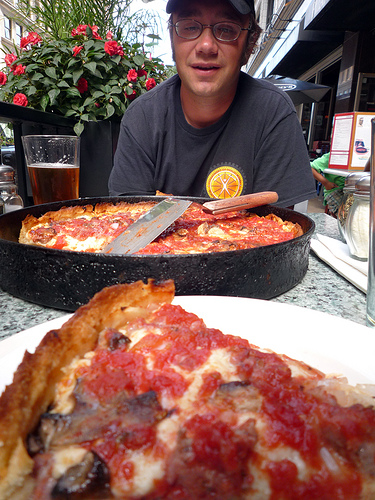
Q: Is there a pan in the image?
A: Yes, there is a pan.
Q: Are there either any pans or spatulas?
A: Yes, there is a pan.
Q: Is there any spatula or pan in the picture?
A: Yes, there is a pan.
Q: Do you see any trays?
A: No, there are no trays.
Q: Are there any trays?
A: No, there are no trays.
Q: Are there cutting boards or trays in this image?
A: No, there are no trays or cutting boards.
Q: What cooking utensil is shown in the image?
A: The cooking utensil is a pan.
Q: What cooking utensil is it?
A: The cooking utensil is a pan.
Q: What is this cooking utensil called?
A: That is a pan.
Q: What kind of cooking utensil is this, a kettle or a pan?
A: That is a pan.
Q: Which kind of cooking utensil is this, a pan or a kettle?
A: That is a pan.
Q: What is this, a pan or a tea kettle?
A: This is a pan.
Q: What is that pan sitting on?
A: The pan is sitting on the pizza.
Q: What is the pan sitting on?
A: The pan is sitting on the pizza.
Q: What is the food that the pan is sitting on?
A: The food is a pizza.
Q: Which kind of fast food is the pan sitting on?
A: The pan is sitting on the pizza.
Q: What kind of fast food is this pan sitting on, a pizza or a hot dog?
A: The pan is sitting on a pizza.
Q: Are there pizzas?
A: Yes, there is a pizza.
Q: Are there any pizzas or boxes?
A: Yes, there is a pizza.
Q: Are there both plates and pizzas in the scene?
A: Yes, there are both a pizza and a plate.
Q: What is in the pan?
A: The pizza is in the pan.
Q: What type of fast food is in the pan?
A: The food is a pizza.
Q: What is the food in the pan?
A: The food is a pizza.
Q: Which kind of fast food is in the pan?
A: The food is a pizza.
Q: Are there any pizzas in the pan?
A: Yes, there is a pizza in the pan.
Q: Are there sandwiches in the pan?
A: No, there is a pizza in the pan.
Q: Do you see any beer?
A: Yes, there is beer.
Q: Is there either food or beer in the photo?
A: Yes, there is beer.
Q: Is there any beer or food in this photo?
A: Yes, there is beer.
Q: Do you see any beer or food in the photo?
A: Yes, there is beer.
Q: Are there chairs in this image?
A: No, there are no chairs.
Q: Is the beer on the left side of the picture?
A: Yes, the beer is on the left of the image.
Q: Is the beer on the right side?
A: No, the beer is on the left of the image.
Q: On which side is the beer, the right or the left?
A: The beer is on the left of the image.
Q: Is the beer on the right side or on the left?
A: The beer is on the left of the image.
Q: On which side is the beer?
A: The beer is on the left of the image.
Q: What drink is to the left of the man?
A: The drink is beer.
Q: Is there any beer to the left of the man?
A: Yes, there is beer to the left of the man.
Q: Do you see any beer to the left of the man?
A: Yes, there is beer to the left of the man.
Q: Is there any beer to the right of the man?
A: No, the beer is to the left of the man.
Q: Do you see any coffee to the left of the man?
A: No, there is beer to the left of the man.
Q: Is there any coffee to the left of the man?
A: No, there is beer to the left of the man.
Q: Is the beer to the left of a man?
A: Yes, the beer is to the left of a man.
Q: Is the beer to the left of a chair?
A: No, the beer is to the left of a man.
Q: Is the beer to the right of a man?
A: No, the beer is to the left of a man.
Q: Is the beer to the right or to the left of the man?
A: The beer is to the left of the man.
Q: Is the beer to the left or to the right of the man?
A: The beer is to the left of the man.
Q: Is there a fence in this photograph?
A: No, there are no fences.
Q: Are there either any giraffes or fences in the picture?
A: No, there are no fences or giraffes.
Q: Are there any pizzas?
A: Yes, there is a pizza.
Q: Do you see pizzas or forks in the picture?
A: Yes, there is a pizza.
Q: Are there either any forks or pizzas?
A: Yes, there is a pizza.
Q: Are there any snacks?
A: No, there are no snacks.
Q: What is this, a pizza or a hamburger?
A: This is a pizza.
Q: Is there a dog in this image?
A: No, there are no dogs.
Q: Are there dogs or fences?
A: No, there are no dogs or fences.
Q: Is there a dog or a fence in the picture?
A: No, there are no dogs or fences.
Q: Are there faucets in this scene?
A: No, there are no faucets.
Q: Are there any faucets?
A: No, there are no faucets.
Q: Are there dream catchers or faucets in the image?
A: No, there are no faucets or dream catchers.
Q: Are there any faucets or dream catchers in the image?
A: No, there are no faucets or dream catchers.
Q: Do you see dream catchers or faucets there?
A: No, there are no faucets or dream catchers.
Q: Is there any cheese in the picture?
A: Yes, there is cheese.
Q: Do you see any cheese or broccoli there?
A: Yes, there is cheese.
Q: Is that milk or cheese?
A: That is cheese.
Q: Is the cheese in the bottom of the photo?
A: Yes, the cheese is in the bottom of the image.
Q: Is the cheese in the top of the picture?
A: No, the cheese is in the bottom of the image.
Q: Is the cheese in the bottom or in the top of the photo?
A: The cheese is in the bottom of the image.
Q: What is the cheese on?
A: The cheese is on the pizza.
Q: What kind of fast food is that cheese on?
A: The cheese is on the pizza.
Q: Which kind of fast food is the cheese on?
A: The cheese is on the pizza.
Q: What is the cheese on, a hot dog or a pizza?
A: The cheese is on a pizza.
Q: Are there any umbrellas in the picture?
A: Yes, there is an umbrella.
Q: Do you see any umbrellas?
A: Yes, there is an umbrella.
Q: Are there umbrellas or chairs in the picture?
A: Yes, there is an umbrella.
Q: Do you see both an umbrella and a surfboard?
A: No, there is an umbrella but no surfboards.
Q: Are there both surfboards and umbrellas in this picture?
A: No, there is an umbrella but no surfboards.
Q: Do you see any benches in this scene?
A: No, there are no benches.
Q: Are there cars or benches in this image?
A: No, there are no benches or cars.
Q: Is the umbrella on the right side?
A: Yes, the umbrella is on the right of the image.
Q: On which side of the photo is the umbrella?
A: The umbrella is on the right of the image.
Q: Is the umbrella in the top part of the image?
A: Yes, the umbrella is in the top of the image.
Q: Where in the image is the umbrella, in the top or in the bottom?
A: The umbrella is in the top of the image.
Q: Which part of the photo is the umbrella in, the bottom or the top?
A: The umbrella is in the top of the image.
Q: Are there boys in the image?
A: No, there are no boys.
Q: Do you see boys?
A: No, there are no boys.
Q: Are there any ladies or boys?
A: No, there are no boys or ladies.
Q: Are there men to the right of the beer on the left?
A: Yes, there is a man to the right of the beer.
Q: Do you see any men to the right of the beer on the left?
A: Yes, there is a man to the right of the beer.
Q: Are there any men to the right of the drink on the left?
A: Yes, there is a man to the right of the beer.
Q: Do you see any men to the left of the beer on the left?
A: No, the man is to the right of the beer.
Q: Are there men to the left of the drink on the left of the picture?
A: No, the man is to the right of the beer.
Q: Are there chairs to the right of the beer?
A: No, there is a man to the right of the beer.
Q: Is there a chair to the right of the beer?
A: No, there is a man to the right of the beer.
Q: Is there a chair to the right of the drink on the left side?
A: No, there is a man to the right of the beer.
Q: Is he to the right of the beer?
A: Yes, the man is to the right of the beer.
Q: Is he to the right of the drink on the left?
A: Yes, the man is to the right of the beer.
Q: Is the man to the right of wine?
A: No, the man is to the right of the beer.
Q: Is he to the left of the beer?
A: No, the man is to the right of the beer.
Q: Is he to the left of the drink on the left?
A: No, the man is to the right of the beer.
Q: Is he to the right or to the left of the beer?
A: The man is to the right of the beer.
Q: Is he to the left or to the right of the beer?
A: The man is to the right of the beer.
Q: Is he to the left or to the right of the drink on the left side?
A: The man is to the right of the beer.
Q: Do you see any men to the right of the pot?
A: Yes, there is a man to the right of the pot.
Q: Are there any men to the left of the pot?
A: No, the man is to the right of the pot.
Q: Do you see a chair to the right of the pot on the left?
A: No, there is a man to the right of the pot.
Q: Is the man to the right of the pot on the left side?
A: Yes, the man is to the right of the pot.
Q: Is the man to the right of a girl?
A: No, the man is to the right of the pot.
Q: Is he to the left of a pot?
A: No, the man is to the right of a pot.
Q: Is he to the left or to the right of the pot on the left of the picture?
A: The man is to the right of the pot.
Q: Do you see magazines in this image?
A: No, there are no magazines.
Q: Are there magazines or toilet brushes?
A: No, there are no magazines or toilet brushes.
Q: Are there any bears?
A: No, there are no bears.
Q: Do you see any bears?
A: No, there are no bears.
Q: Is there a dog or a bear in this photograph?
A: No, there are no bears or dogs.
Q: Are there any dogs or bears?
A: No, there are no bears or dogs.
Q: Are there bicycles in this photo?
A: No, there are no bicycles.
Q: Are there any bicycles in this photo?
A: No, there are no bicycles.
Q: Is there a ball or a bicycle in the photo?
A: No, there are no bicycles or balls.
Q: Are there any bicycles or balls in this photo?
A: No, there are no bicycles or balls.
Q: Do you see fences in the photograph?
A: No, there are no fences.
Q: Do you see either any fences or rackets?
A: No, there are no fences or rackets.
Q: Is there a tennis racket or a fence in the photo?
A: No, there are no fences or rackets.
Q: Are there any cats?
A: No, there are no cats.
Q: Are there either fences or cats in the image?
A: No, there are no cats or fences.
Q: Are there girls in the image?
A: No, there are no girls.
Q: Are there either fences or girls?
A: No, there are no girls or fences.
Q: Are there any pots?
A: Yes, there is a pot.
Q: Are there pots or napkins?
A: Yes, there is a pot.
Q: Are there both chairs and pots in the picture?
A: No, there is a pot but no chairs.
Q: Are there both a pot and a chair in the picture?
A: No, there is a pot but no chairs.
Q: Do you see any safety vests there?
A: No, there are no safety vests.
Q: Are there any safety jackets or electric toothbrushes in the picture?
A: No, there are no safety jackets or electric toothbrushes.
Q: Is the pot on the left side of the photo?
A: Yes, the pot is on the left of the image.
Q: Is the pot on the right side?
A: No, the pot is on the left of the image.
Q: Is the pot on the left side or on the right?
A: The pot is on the left of the image.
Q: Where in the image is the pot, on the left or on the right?
A: The pot is on the left of the image.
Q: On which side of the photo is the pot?
A: The pot is on the left of the image.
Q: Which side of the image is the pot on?
A: The pot is on the left of the image.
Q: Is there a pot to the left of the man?
A: Yes, there is a pot to the left of the man.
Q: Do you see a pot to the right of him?
A: No, the pot is to the left of the man.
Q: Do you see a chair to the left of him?
A: No, there is a pot to the left of the man.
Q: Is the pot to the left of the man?
A: Yes, the pot is to the left of the man.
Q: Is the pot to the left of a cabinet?
A: No, the pot is to the left of the man.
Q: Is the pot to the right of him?
A: No, the pot is to the left of the man.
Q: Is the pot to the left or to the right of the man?
A: The pot is to the left of the man.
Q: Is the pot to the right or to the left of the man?
A: The pot is to the left of the man.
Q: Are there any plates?
A: Yes, there is a plate.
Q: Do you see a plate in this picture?
A: Yes, there is a plate.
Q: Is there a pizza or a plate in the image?
A: Yes, there is a plate.